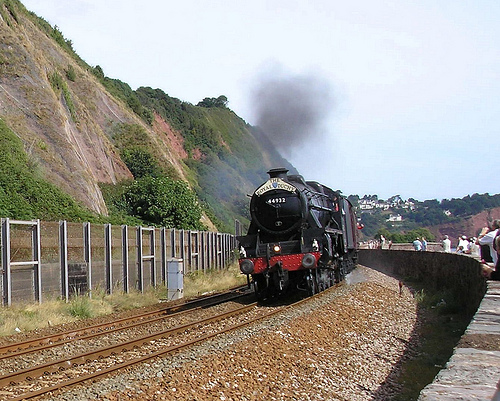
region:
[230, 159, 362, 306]
The train on the tracks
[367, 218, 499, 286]
The people on the walkway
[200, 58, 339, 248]
The smoke above the train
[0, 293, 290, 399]
The tracks in front of the train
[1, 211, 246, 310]
The large fence next to the train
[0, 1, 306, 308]
The hill next to the train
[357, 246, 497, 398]
The short wall next to the train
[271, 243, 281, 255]
The headlight on the front of the train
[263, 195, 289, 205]
The number on the front of the train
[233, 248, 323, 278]
The red plate on the front of the train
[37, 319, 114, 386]
two parallel train tracks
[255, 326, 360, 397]
drainage slope next to a set of train tracks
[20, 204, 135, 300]
fence blocking off a set of train tracks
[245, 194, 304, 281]
front of a moving train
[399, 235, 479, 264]
people standing next to a set of train tracks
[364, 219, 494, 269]
people watching the train go by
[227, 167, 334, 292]
black train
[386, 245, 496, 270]
barrier next to a set of train tracks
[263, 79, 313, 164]
smoke from the moving train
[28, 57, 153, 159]
cliff next to the train tracks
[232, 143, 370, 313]
front of a black train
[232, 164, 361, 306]
black and red train engine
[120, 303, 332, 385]
tan train track and tan gravel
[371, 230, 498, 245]
people next to train track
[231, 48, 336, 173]
cloud of black smoke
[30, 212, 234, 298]
fence with white posts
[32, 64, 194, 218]
bushes growing on mountainside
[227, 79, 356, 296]
black smoke coming from train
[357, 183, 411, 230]
white buildings on mountainside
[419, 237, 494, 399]
stone wall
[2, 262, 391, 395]
a set of rusty tracks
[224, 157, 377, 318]
a long black train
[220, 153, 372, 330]
a black steam engine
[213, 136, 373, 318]
a train travels the track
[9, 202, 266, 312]
a long barrier fence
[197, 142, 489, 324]
a crowd watches a train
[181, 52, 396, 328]
smoke rises from a train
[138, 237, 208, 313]
a train signal box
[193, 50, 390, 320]
a large black steam engine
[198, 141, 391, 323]
a large black locomotive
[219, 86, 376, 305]
black train engine on tracks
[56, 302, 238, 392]
rusted old train tracks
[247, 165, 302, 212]
logo for the Royal Duchy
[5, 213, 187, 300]
fence behind train tracks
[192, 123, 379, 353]
Royal Duchy train on tour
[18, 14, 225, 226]
large cliffs behind tracks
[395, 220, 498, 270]
people watching train pass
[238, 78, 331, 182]
smoke from train engine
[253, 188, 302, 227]
number of train engine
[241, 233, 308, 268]
headlight on northbound train